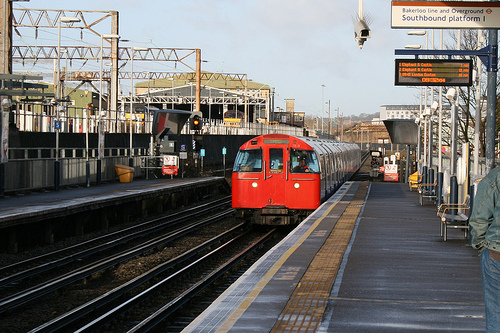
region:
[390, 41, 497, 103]
A train sign at a station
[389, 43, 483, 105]
a sign at a rail station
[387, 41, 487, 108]
sign at a railway station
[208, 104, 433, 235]
a red train at a train station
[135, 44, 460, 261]
a red train at a railway station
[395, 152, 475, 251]
seating at a railway station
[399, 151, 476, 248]
seating at a train station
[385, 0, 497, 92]
signage at a railway station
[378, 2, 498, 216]
signs at a train station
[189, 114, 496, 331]
the platform at a railway station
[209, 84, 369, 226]
this is a train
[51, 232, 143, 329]
this is a railway line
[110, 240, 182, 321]
this is a railway line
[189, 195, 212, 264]
this is a railway line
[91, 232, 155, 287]
this is a railway line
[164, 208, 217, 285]
this is a railway line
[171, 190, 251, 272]
this is a railway line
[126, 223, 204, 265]
this is a railway line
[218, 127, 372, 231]
A red commuter train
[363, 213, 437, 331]
A gray concrete sidewalk surface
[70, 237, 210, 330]
Silver metal train tracks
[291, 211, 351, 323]
A yellow brick ground surface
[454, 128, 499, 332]
A man wearing blue jeans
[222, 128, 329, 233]
The front of a train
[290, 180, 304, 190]
A headlight on a train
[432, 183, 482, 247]
A metal bench on a train platform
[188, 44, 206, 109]
A gray metal pole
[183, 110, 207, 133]
A yellow traffic light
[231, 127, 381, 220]
A red train on the track.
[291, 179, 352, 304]
A yellow line on the platform.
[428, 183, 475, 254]
A bench on the platform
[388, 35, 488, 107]
A black and orange sign.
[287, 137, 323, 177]
A person on the train.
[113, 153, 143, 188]
A yellow bucket on the platform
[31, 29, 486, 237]
The train is parked at the station.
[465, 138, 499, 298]
A man waiting on the train.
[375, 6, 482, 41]
A white sign hanging from the pole.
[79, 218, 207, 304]
Tracks on the ground.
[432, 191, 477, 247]
the bench on the train platform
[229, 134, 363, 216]
the red train on the pulling into the platform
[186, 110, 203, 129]
the traffic signal on the pole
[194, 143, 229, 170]
the signs on the train platform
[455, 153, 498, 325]
part of the man on the platform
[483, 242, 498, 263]
the brown tag on the jeans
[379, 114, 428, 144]
the panel on the train platform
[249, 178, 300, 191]
the light on the front of the train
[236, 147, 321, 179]
the windshield of the train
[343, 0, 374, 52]
the white camera hanging overhead